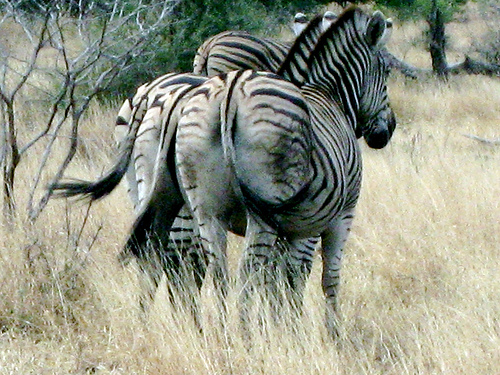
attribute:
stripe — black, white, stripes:
[250, 86, 305, 141]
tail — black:
[211, 108, 315, 241]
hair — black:
[300, 5, 364, 69]